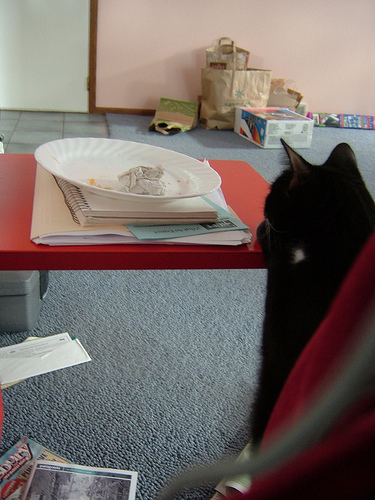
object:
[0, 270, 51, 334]
safe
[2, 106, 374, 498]
floor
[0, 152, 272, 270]
table top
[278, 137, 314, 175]
ear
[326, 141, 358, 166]
ear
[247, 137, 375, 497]
cat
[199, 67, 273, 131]
bag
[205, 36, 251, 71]
bag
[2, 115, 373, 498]
carpet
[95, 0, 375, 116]
wall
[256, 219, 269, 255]
front paw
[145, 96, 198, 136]
bags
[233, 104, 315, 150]
box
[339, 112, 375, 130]
box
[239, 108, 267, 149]
picture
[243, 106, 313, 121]
picture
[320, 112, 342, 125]
picture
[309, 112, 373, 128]
picture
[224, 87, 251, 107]
picture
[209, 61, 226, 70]
picture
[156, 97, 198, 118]
picture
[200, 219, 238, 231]
picture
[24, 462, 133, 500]
picture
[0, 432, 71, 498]
picture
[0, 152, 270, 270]
table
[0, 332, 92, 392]
mail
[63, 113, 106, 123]
floor tile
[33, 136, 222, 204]
plate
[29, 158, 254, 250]
folder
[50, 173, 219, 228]
notebook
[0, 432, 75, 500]
booklet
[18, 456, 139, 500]
booklet